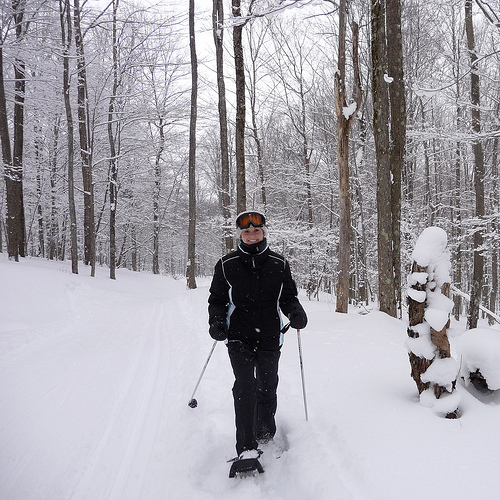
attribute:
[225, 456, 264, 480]
shoe — black